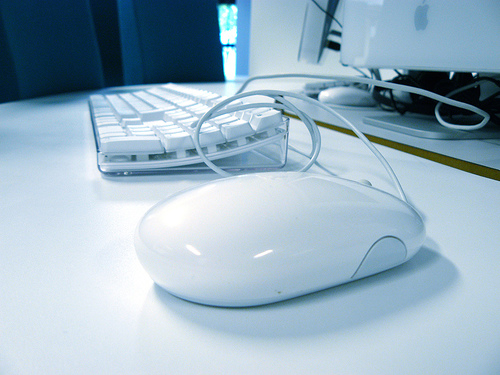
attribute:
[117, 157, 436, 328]
mouse — white, present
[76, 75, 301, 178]
keyboard — white, existing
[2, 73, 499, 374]
table — white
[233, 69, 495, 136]
cord — white